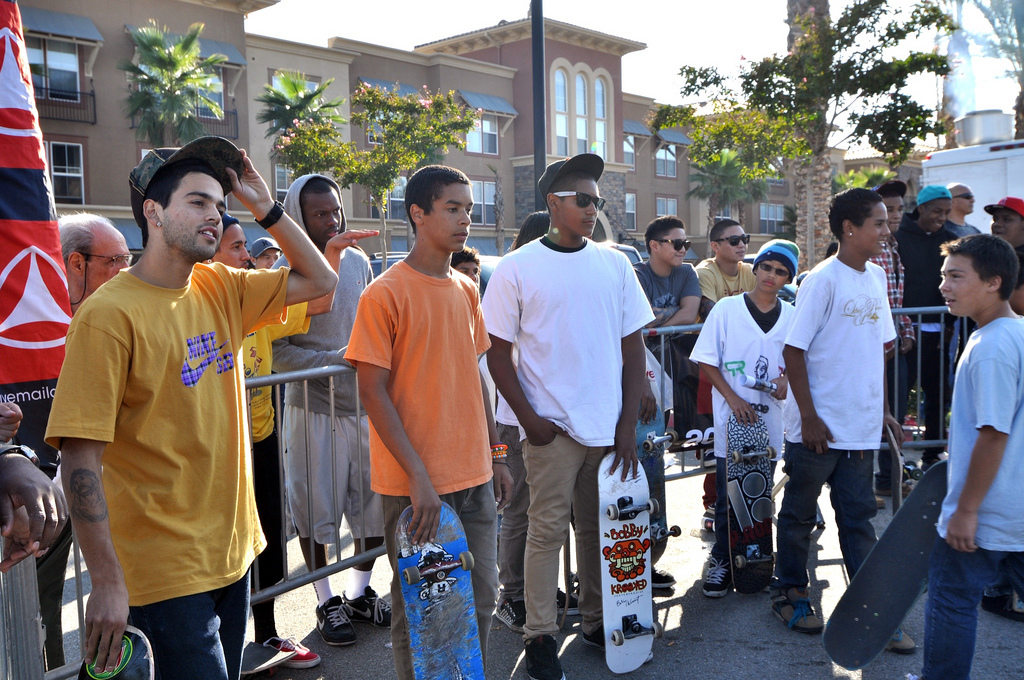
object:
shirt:
[41, 262, 311, 606]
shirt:
[339, 264, 507, 496]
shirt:
[481, 236, 657, 447]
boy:
[926, 232, 1021, 678]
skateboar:
[392, 500, 480, 680]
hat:
[127, 136, 248, 207]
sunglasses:
[550, 191, 607, 211]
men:
[697, 217, 758, 303]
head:
[130, 143, 233, 253]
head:
[400, 166, 480, 250]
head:
[539, 166, 610, 237]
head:
[751, 240, 801, 292]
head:
[826, 188, 891, 256]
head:
[935, 231, 1024, 314]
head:
[643, 214, 694, 266]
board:
[595, 452, 667, 674]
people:
[265, 175, 396, 644]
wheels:
[403, 566, 422, 584]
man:
[30, 136, 335, 680]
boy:
[355, 165, 512, 680]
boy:
[479, 151, 668, 672]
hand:
[404, 483, 445, 544]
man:
[479, 152, 671, 676]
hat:
[752, 237, 802, 281]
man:
[692, 236, 805, 600]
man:
[342, 162, 518, 676]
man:
[474, 160, 669, 675]